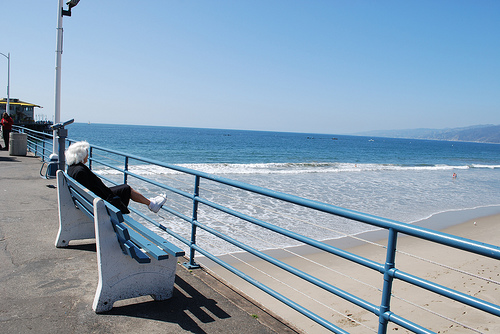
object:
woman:
[62, 138, 166, 216]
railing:
[0, 125, 500, 333]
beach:
[195, 206, 499, 270]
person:
[1, 114, 13, 150]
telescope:
[50, 118, 77, 175]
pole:
[53, 1, 65, 179]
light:
[63, 1, 82, 17]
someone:
[451, 170, 457, 179]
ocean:
[33, 122, 500, 256]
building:
[1, 97, 43, 125]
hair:
[64, 140, 90, 166]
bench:
[55, 169, 186, 313]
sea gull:
[473, 220, 477, 228]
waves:
[99, 159, 500, 175]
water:
[32, 121, 500, 258]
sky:
[0, 0, 500, 143]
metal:
[54, 18, 66, 173]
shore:
[400, 204, 498, 223]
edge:
[465, 214, 500, 221]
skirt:
[110, 184, 132, 216]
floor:
[0, 148, 299, 333]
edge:
[164, 239, 188, 257]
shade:
[0, 155, 19, 162]